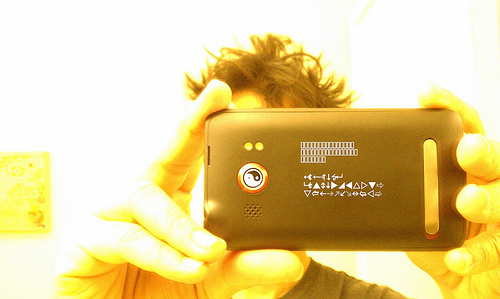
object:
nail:
[193, 231, 223, 251]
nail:
[178, 258, 207, 277]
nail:
[456, 129, 500, 172]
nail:
[454, 184, 499, 220]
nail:
[444, 246, 476, 273]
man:
[57, 33, 500, 298]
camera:
[233, 161, 271, 197]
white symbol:
[377, 189, 383, 196]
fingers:
[210, 248, 310, 299]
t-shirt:
[282, 256, 401, 297]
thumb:
[211, 238, 313, 299]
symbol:
[303, 173, 387, 198]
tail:
[358, 180, 365, 189]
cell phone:
[203, 106, 462, 250]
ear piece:
[243, 203, 264, 219]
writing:
[292, 172, 402, 206]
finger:
[92, 220, 207, 285]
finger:
[126, 178, 227, 264]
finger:
[181, 165, 199, 195]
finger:
[151, 78, 232, 195]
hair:
[184, 32, 351, 109]